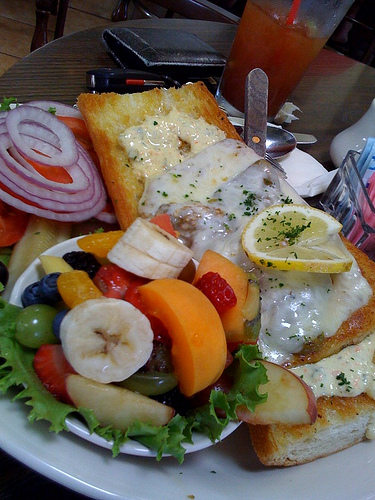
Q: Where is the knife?
A: Under food.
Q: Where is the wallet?
A: Table.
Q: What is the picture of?
A: Food.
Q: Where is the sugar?
A: Packets on right.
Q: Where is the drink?
A: Top right.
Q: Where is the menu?
A: No menu.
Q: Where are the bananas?
A: In fruit salad.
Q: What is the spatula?
A: No spatula.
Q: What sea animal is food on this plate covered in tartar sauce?
A: Fish.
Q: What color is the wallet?
A: Black.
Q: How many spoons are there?
A: One.